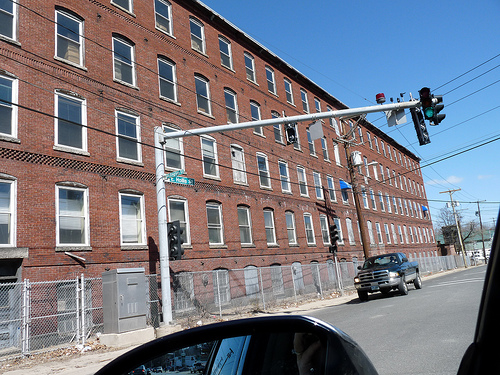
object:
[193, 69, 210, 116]
window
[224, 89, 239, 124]
window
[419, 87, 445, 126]
light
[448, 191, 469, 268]
poles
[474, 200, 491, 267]
poles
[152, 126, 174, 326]
metal pole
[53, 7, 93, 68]
window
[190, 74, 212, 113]
window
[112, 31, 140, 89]
window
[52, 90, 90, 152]
window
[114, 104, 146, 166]
window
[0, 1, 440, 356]
building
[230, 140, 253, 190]
window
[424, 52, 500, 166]
wires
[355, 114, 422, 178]
wires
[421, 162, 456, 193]
wires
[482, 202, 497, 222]
wires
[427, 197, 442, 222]
wires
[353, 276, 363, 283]
headlights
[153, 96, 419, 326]
pole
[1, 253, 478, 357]
fence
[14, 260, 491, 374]
sidewalk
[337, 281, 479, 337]
ground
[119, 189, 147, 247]
window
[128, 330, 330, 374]
reflection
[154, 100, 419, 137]
bar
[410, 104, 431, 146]
lights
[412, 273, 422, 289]
wheel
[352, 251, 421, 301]
truck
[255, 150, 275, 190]
window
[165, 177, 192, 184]
sign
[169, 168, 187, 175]
sign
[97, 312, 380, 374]
mirror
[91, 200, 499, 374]
car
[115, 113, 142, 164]
window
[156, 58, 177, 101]
rectangular window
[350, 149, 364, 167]
transformer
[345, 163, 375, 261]
pole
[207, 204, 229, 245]
window